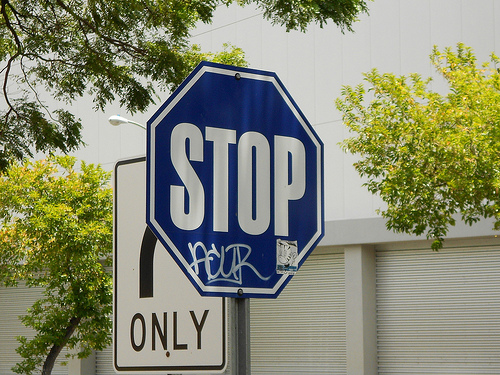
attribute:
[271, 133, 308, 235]
letter — white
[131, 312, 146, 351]
letter — black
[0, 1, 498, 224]
sky — clear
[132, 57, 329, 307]
sign — light colored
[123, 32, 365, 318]
sign — eight sided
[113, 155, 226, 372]
sign — black, white, right turn only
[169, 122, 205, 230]
letter — white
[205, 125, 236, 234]
letter — white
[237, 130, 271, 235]
letter — white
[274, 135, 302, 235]
letter — white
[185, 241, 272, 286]
letter — white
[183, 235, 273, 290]
graffiti — white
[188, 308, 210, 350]
letter — black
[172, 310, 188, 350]
letter — black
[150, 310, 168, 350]
letter — black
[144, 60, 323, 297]
sign — white, blue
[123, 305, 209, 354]
word — white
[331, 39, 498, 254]
leaves — light colored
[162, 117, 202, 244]
letter — white